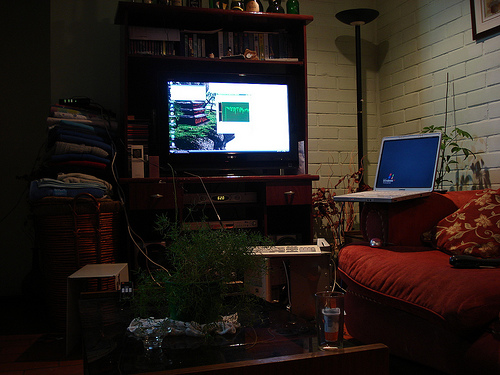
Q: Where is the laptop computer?
A: On the arm of the chair.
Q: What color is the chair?
A: Red.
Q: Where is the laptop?
A: On the couch.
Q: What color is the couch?
A: Red.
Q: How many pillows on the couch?
A: One.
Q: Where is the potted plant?
A: On the table.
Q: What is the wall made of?
A: Bricks.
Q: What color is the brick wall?
A: White.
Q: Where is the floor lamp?
A: In the corner.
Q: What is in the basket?
A: Clothes.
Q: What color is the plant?
A: Green.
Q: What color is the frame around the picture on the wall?
A: Black.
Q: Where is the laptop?
A: On the arm of the couch.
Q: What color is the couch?
A: Red.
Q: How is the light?
A: Turned off.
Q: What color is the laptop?
A: Silver.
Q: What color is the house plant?
A: Green.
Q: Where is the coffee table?
A: In front of the coffee table.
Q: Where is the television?
A: On the entertainment center.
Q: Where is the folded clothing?
A: On the wicker basket.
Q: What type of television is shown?
A: A flat screen.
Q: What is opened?
A: A laptop.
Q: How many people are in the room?
A: Zero.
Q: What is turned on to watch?
A: The television.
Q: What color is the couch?
A: Red.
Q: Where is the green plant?
A: On the table.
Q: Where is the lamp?
A: In the corner.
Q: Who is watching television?
A: No one.